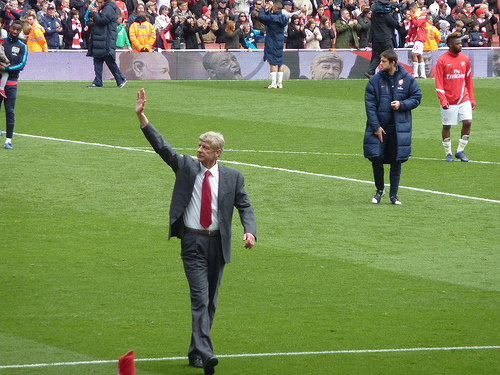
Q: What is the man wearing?
A: A suit.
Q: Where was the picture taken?
A: On a soccer field.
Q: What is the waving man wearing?
A: A suit.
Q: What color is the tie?
A: Red.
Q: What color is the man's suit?
A: Gray.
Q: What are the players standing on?
A: Grass.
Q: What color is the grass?
A: Green.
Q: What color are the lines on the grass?
A: White.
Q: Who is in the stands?
A: Fans.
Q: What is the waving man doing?
A: Walking.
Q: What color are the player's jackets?
A: Blue.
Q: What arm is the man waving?
A: Right.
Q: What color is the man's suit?
A: Gray.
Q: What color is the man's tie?
A: Red.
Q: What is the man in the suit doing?
A: Waving.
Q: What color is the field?
A: Green.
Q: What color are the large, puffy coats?
A: Blue.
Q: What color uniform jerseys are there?
A: Red.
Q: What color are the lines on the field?
A: White.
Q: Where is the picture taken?
A: On the field.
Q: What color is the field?
A: Green.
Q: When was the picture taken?
A: Daytime.